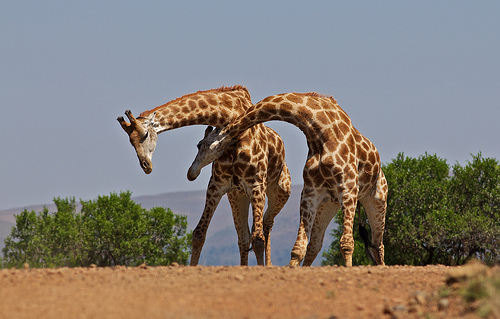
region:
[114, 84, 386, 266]
Two giraffes playing together.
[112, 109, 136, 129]
Horns on a giraffes head to the left of another giraffe.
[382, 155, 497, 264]
Green trees to the right of two giraffes.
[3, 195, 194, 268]
Green tree tops to the left of giraffes.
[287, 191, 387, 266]
Four legs of a giraffe to the left of another giraffe.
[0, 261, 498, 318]
Brown dirt on the ground in front of giraffes playing.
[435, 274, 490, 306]
Green grass up in the brown dirt.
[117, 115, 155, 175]
Head of a giraffe to the left of another giraffe.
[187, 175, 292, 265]
Four legs on a giraffe to the right of another giraffe.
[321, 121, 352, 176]
Spots on a giraffe's body.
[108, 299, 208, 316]
The ground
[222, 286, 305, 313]
The ground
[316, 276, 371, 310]
The ground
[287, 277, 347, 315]
The ground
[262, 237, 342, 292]
The ground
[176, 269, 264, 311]
The ground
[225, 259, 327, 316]
The ground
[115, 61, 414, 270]
two giraffe in a field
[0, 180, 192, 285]
tree with green leaves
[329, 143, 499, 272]
tree with green leaves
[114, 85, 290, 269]
giraffe in a field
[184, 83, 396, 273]
giraffe in a field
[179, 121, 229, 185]
head of a giraffe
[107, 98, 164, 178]
head of a giraffe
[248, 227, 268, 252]
knobby knee on a giraffe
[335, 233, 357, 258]
knobby knee on a giraffe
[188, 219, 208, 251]
knobby knee on a giraffe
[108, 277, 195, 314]
The ground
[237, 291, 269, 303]
The ground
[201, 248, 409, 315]
The ground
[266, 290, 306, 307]
The ground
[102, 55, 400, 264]
Two giraffes standing up.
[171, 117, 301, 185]
Giraffees head touchin belly.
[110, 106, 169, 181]
Giraffee looking at ground.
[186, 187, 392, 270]
Eight legs for the giraffes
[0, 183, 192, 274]
A bush on the ground.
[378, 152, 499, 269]
Another bush on the ground.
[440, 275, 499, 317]
Grass sprouting from dirt.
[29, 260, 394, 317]
Dirt all over the ground.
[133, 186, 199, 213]
Hills in the distance.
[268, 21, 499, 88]
The sky is blue.